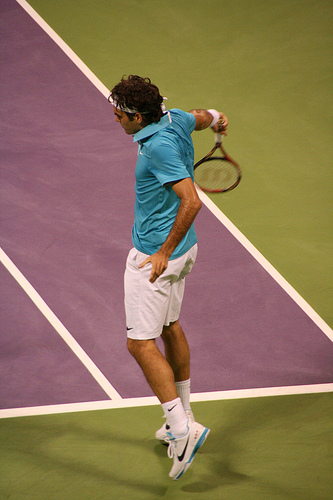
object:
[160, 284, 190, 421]
leg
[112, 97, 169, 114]
sweatband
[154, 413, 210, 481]
shoes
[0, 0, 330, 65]
multiple colors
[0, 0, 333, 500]
court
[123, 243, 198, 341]
shorts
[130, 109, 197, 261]
shirt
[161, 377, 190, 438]
socks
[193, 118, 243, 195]
racket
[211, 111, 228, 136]
hand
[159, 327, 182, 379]
shadow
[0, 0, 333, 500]
ground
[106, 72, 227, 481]
player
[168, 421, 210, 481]
shoe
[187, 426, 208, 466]
blue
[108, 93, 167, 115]
head band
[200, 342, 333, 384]
purple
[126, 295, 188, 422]
leg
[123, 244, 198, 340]
man's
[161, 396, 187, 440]
sock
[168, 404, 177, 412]
checkmark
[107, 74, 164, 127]
hair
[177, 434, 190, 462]
checkmark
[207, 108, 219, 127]
sweatband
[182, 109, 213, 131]
arm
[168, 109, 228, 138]
motion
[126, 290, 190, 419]
legs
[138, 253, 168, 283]
hand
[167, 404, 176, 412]
logo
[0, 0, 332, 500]
turf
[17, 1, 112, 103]
lines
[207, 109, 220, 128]
wristband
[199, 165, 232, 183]
logo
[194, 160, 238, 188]
netting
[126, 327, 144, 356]
knee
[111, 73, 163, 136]
head